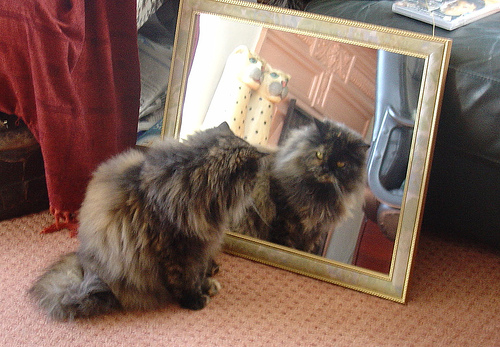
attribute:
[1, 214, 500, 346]
carpet — pink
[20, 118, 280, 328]
cat — fluffy, brown, fuzzy, grey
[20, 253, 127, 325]
tail — bushy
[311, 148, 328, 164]
eye — green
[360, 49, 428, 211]
chair — back, leather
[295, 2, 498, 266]
couch — leather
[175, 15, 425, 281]
mirror — square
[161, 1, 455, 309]
frame — gold, nice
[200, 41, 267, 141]
statue — cat, polka dotted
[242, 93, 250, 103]
polka dot — black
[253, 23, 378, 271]
mantle — pink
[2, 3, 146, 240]
curtain — red, burgundy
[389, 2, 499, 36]
picture — face